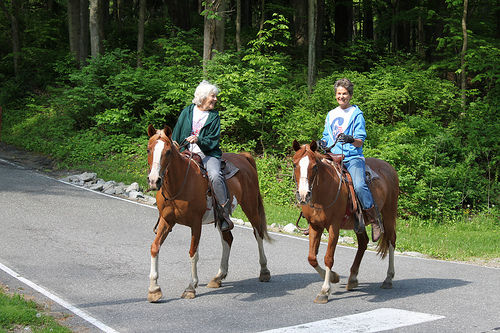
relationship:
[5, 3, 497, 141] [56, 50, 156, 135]
wooded area behind tree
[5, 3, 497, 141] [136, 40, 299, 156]
wooded area behind tree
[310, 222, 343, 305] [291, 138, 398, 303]
leg of horse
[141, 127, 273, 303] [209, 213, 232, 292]
horse has leg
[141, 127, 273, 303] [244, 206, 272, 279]
horse has leg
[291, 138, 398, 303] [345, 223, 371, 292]
horse has leg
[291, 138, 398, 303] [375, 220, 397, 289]
horse has leg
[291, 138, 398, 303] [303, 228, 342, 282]
horse has leg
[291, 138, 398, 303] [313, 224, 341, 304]
horse has leg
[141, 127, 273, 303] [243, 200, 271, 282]
horse has leg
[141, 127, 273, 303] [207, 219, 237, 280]
horse has leg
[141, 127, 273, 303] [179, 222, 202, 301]
horse has leg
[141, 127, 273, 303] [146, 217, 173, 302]
horse has leg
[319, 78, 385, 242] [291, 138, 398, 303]
woman riding horse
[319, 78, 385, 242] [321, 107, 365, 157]
woman wearing shirt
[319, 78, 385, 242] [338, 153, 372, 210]
woman wearing pants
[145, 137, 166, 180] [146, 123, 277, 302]
blaze on chestnut horse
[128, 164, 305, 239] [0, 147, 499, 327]
horse crossing road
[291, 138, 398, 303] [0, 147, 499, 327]
horse crossing road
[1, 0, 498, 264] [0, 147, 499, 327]
forest behind road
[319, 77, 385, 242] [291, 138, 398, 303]
person riding horse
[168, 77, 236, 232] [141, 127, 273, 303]
woman riding horse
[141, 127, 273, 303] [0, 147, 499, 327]
horse crossing road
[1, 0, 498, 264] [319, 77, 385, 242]
forest behind person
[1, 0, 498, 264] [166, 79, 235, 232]
forest behind lady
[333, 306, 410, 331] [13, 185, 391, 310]
white marker painted on road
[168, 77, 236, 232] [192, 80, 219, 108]
woman has hair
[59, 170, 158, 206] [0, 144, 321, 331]
rocks along side of road.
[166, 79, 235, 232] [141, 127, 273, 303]
lady riding horse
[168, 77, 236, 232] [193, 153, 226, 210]
woman wearing pants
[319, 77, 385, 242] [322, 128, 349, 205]
person holding reigns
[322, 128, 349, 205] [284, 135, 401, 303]
reigns on horse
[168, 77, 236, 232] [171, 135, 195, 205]
woman holding reigns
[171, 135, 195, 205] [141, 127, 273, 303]
reigns on horse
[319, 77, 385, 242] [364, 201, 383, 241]
person wearing boot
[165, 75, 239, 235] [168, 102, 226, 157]
woman wearing cardigan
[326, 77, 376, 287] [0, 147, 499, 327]
woman crossing a road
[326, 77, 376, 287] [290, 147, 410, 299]
woman riding a horse